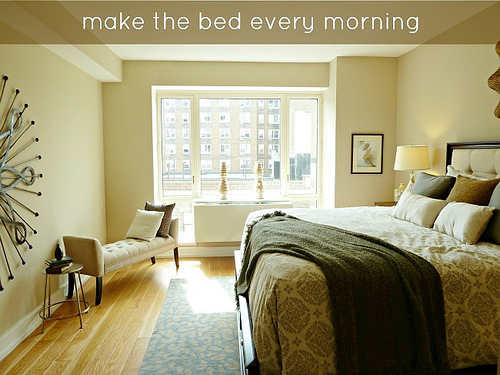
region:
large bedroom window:
[152, 85, 321, 206]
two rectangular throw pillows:
[392, 190, 494, 242]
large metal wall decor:
[0, 75, 42, 290]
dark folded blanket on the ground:
[238, 210, 448, 369]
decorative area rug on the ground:
[139, 277, 238, 374]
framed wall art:
[349, 134, 385, 174]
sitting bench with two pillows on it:
[67, 204, 177, 304]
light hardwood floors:
[1, 258, 229, 373]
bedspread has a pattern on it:
[247, 207, 497, 369]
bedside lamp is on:
[393, 144, 430, 184]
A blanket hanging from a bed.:
[238, 204, 429, 373]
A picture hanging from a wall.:
[343, 136, 385, 190]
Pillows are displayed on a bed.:
[396, 176, 498, 236]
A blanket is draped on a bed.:
[245, 217, 399, 287]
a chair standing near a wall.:
[87, 178, 186, 271]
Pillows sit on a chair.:
[111, 202, 183, 264]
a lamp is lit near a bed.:
[379, 135, 439, 183]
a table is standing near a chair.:
[41, 245, 97, 330]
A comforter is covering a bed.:
[288, 218, 493, 295]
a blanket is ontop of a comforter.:
[243, 198, 415, 330]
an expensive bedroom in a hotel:
[35, 67, 482, 321]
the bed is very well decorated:
[243, 175, 499, 353]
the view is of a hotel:
[137, 58, 354, 219]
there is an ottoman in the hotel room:
[27, 189, 214, 319]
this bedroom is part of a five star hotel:
[71, 147, 467, 332]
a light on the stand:
[391, 132, 437, 191]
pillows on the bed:
[382, 170, 497, 255]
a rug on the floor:
[150, 268, 259, 374]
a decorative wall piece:
[0, 79, 48, 301]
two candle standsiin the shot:
[212, 157, 289, 196]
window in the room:
[161, 94, 317, 182]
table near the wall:
[26, 261, 96, 323]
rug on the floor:
[150, 273, 220, 374]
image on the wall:
[341, 120, 389, 182]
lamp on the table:
[392, 136, 433, 188]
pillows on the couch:
[131, 195, 176, 240]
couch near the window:
[61, 203, 189, 287]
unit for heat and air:
[189, 195, 293, 244]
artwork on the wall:
[2, 64, 36, 284]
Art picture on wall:
[351, 131, 383, 174]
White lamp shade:
[395, 145, 427, 170]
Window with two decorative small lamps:
[151, 86, 324, 204]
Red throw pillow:
[451, 175, 492, 204]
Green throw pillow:
[406, 174, 448, 196]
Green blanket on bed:
[242, 205, 444, 372]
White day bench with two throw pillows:
[64, 201, 195, 279]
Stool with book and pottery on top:
[35, 244, 90, 335]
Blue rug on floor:
[158, 276, 237, 372]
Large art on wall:
[0, 79, 40, 316]